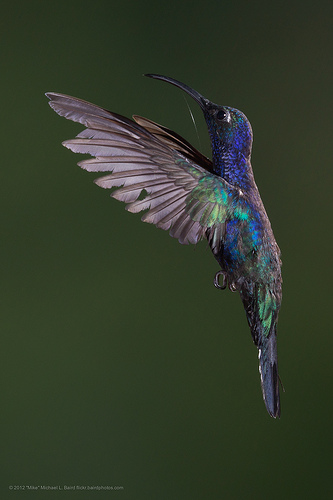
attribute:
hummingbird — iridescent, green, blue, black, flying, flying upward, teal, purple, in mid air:
[45, 73, 286, 420]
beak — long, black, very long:
[143, 72, 204, 113]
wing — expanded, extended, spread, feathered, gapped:
[45, 90, 229, 251]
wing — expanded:
[130, 116, 217, 183]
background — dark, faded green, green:
[1, 0, 330, 499]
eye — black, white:
[215, 110, 227, 122]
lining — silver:
[214, 107, 232, 125]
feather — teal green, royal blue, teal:
[214, 187, 226, 207]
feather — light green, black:
[202, 203, 219, 229]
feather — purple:
[249, 217, 262, 247]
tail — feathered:
[244, 297, 282, 418]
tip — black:
[256, 356, 284, 417]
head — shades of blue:
[204, 104, 252, 163]